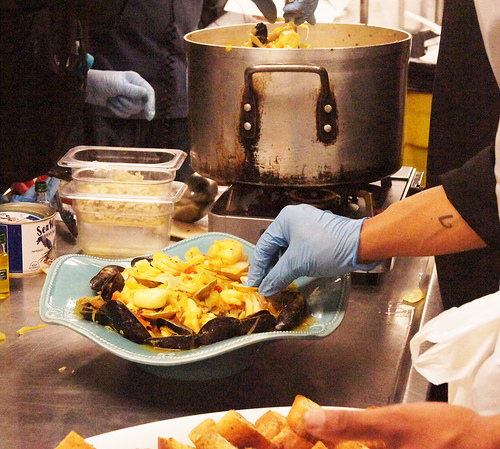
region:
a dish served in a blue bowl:
[36, 238, 351, 378]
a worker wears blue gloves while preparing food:
[250, 198, 383, 296]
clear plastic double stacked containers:
[58, 146, 189, 256]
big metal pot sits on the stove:
[180, 20, 411, 187]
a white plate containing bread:
[53, 390, 378, 447]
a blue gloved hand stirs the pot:
[250, 3, 321, 51]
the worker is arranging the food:
[245, 203, 378, 298]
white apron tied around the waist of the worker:
[403, 300, 498, 402]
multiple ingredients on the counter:
[1, 176, 58, 300]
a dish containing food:
[65, 142, 182, 165]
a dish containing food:
[44, 189, 186, 196]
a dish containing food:
[83, 208, 179, 259]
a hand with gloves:
[85, 67, 159, 117]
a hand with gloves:
[250, 195, 362, 291]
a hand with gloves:
[275, 0, 315, 21]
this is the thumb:
[318, 411, 471, 444]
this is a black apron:
[448, 58, 463, 115]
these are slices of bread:
[216, 400, 306, 445]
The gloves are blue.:
[243, 188, 360, 312]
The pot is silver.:
[173, 11, 420, 173]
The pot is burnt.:
[186, 145, 400, 205]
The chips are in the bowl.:
[93, 225, 277, 352]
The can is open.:
[3, 191, 60, 291]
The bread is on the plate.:
[75, 393, 399, 445]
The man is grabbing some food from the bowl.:
[52, 144, 496, 385]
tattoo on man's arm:
[434, 209, 462, 242]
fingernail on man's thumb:
[304, 408, 328, 426]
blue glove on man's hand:
[248, 204, 382, 295]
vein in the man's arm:
[409, 225, 442, 248]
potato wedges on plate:
[219, 412, 273, 446]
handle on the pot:
[232, 62, 343, 86]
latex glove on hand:
[87, 62, 157, 131]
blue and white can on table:
[1, 199, 56, 275]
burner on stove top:
[239, 186, 369, 212]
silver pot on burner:
[172, 17, 425, 191]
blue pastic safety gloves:
[241, 193, 380, 305]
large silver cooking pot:
[178, 8, 412, 186]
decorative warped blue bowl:
[36, 208, 356, 380]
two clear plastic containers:
[52, 128, 186, 247]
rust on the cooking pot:
[217, 91, 349, 176]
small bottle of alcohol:
[0, 229, 14, 301]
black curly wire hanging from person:
[149, 2, 189, 148]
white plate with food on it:
[82, 400, 402, 447]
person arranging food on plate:
[92, 190, 377, 363]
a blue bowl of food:
[35, 228, 358, 368]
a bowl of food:
[37, 228, 354, 378]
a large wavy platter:
[33, 233, 365, 370]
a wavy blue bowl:
[35, 228, 358, 365]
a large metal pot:
[181, 11, 416, 189]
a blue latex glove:
[248, 196, 375, 307]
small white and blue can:
[0, 203, 65, 281]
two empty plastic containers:
[59, 138, 189, 263]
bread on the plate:
[263, 408, 291, 448]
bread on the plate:
[221, 405, 250, 444]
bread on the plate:
[201, 408, 216, 448]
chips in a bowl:
[188, 285, 226, 317]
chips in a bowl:
[241, 278, 270, 310]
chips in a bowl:
[197, 245, 244, 292]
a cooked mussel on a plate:
[96, 296, 147, 348]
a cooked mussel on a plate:
[239, 311, 274, 338]